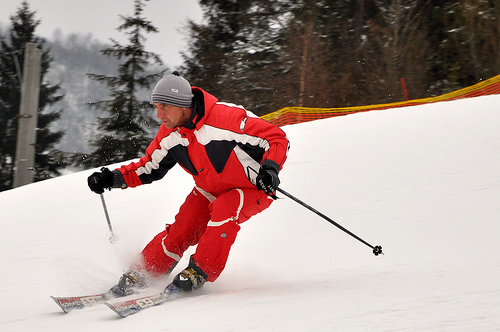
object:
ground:
[0, 138, 493, 329]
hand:
[255, 160, 280, 190]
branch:
[279, 26, 322, 82]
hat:
[149, 74, 193, 107]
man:
[50, 74, 386, 315]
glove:
[255, 158, 283, 193]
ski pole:
[99, 195, 119, 244]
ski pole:
[274, 184, 386, 261]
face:
[155, 103, 183, 127]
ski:
[52, 292, 107, 312]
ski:
[104, 294, 163, 314]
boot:
[168, 261, 207, 293]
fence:
[279, 77, 498, 121]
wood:
[19, 41, 42, 182]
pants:
[142, 195, 267, 279]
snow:
[396, 119, 477, 191]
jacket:
[115, 92, 291, 201]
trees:
[81, 1, 163, 161]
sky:
[62, 5, 107, 28]